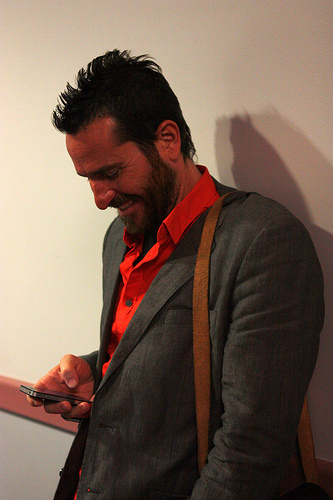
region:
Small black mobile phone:
[18, 371, 102, 421]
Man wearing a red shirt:
[39, 32, 281, 499]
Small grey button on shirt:
[119, 295, 141, 320]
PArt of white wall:
[255, 14, 284, 44]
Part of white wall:
[291, 112, 317, 197]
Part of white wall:
[212, 8, 241, 35]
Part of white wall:
[18, 422, 34, 440]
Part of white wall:
[10, 450, 34, 465]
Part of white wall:
[38, 435, 63, 449]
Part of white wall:
[7, 480, 28, 499]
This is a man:
[36, 54, 293, 483]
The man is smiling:
[47, 68, 223, 231]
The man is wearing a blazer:
[68, 207, 312, 495]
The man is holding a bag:
[192, 198, 317, 490]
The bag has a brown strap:
[187, 193, 322, 488]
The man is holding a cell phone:
[20, 360, 94, 420]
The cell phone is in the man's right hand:
[22, 358, 106, 425]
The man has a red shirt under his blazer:
[106, 183, 207, 380]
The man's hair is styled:
[37, 46, 227, 152]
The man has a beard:
[140, 165, 175, 231]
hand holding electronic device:
[18, 345, 103, 424]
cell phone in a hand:
[19, 349, 99, 428]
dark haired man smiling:
[51, 47, 199, 250]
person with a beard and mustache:
[30, 54, 234, 400]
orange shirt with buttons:
[94, 164, 216, 385]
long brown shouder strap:
[189, 183, 222, 486]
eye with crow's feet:
[96, 154, 141, 183]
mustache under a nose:
[84, 182, 143, 211]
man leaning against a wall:
[32, 33, 332, 498]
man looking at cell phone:
[11, 50, 195, 421]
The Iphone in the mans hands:
[20, 385, 91, 406]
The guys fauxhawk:
[51, 42, 161, 128]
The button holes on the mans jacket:
[86, 488, 102, 496]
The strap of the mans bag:
[196, 190, 239, 483]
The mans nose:
[88, 180, 114, 210]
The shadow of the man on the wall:
[207, 104, 331, 201]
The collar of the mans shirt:
[160, 162, 225, 245]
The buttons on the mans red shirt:
[126, 297, 131, 306]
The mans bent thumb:
[61, 354, 80, 387]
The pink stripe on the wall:
[0, 376, 87, 434]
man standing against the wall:
[41, 46, 309, 496]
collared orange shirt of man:
[96, 169, 216, 372]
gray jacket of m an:
[44, 191, 328, 498]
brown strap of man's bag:
[191, 190, 319, 477]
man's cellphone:
[19, 379, 87, 407]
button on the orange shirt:
[125, 295, 134, 306]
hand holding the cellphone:
[27, 357, 95, 421]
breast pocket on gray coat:
[163, 302, 212, 353]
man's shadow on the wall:
[210, 105, 331, 451]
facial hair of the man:
[110, 145, 178, 234]